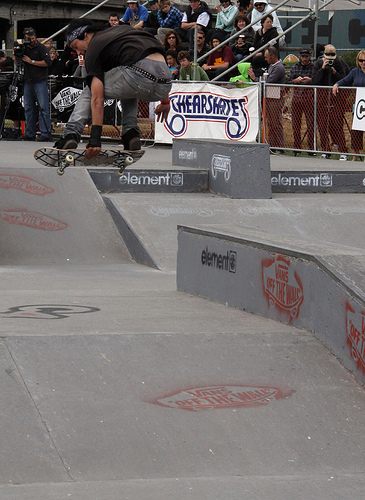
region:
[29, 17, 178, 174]
a person doing a skateboard trick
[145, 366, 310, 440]
vans logo painted on the ramps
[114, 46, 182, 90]
the mans boxers sticking out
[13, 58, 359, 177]
a metal chain link fence to keep people back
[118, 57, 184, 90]
a black studded belt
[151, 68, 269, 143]
a white sign hanging on the fence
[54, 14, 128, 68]
a man wearing a blue headband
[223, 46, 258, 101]
young person wearing a bright green jacket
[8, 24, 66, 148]
a man video taping the skateboarder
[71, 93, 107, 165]
a black wrist band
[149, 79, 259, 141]
white banner that says Cheapskates in blue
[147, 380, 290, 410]
red graffiti that says Vans Off the Wall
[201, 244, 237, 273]
black graffiti that says element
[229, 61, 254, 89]
kid in bright green rain coat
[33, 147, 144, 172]
skateboard white with black stripes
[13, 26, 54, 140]
man in black shirt videotaping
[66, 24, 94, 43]
black bandana worn by skateboarder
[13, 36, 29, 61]
black large video camera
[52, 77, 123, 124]
black banner that says Vans Off the Wall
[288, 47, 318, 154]
man standing in black and grey checkered flannel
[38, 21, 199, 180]
doing a trick on the skateboard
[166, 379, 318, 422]
logo on the ground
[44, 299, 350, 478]
floor made of concrete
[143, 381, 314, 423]
red logo on the ground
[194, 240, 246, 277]
black logo on the wall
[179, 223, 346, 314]
wall made of concrete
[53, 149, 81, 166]
wheel of the skateboard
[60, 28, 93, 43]
blue bandana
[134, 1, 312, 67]
the crowd is enjoying the show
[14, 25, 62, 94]
camera man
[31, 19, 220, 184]
Skateboarder with a black shirt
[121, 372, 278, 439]
Red spray painted logo on the grey ramp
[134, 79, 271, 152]
Red, blue, and white sign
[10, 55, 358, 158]
Grey chain link fence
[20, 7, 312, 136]
People sitting on bleachers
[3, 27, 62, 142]
Man with a camera recording the skateboarder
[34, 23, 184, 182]
The skateboarder holds his board with one hand while in mid-air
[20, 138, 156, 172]
The skateboard has white wheels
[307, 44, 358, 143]
A woman is taking a picture with her camera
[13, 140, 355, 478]
The course is grey with red and black logos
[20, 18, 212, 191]
man riding a skate board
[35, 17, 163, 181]
man with long black hair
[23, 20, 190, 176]
man wearing a sweat band around his hair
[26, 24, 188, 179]
man wearing black short sleeve pullover shirt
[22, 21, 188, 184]
man wear gray denim jeans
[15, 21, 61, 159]
man wearing a pair of blue jeans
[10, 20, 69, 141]
man taking pictures with a camera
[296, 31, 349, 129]
man in the audience wearing a football helmet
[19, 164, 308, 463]
concrete skate ramps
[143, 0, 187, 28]
boy with blue plaid long sleeve shirt